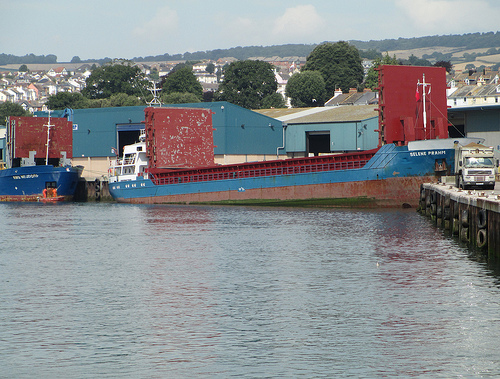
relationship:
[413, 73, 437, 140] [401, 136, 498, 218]
flagstaff on ship bow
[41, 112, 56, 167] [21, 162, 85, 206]
flagstaff on ship bow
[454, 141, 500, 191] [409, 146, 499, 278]
truck on dock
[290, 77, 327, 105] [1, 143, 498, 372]
trees behind port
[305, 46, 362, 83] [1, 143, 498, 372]
trees behind port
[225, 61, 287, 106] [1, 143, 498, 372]
trees behind port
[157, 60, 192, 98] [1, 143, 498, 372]
trees behind port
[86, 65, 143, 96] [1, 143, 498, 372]
trees behind port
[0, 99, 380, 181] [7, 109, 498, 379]
building behind port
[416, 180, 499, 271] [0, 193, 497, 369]
bridge over water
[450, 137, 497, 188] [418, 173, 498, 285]
truck on bridge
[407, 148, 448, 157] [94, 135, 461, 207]
words on boat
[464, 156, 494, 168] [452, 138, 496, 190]
windshield on truck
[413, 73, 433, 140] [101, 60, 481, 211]
flagstaff on boat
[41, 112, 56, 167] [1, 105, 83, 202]
flagstaff on boat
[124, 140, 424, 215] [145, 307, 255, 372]
blue ship in water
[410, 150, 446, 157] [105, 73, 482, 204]
words on side of boat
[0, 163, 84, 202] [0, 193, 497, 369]
blue boat in water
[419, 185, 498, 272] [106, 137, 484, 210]
bridge beside blue ship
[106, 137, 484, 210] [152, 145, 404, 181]
blue ship has red decking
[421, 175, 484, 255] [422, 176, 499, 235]
dock has wooden pilings